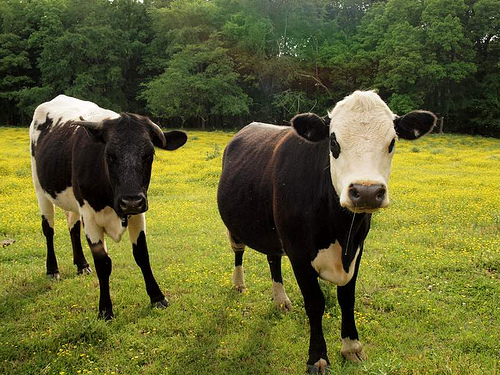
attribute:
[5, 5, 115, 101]
tree — evergreen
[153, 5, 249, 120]
tree — evergreen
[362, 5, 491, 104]
tree — evergreen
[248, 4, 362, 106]
tree — evergreen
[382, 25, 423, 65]
leaves — green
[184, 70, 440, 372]
cow — black, white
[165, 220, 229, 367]
grass — green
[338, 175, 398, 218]
nose — gray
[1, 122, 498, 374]
grass — green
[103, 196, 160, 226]
muzzle — black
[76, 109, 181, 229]
head — black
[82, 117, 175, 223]
head — black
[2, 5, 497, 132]
area — wooded 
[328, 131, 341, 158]
eye — black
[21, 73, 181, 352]
cow — White, black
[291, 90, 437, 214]
head — white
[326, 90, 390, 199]
face — white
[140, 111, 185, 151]
horn — curved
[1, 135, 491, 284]
flowers — yellow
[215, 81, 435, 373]
cow — white, black, black and white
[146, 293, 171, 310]
hoof — black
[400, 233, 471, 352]
grass — green